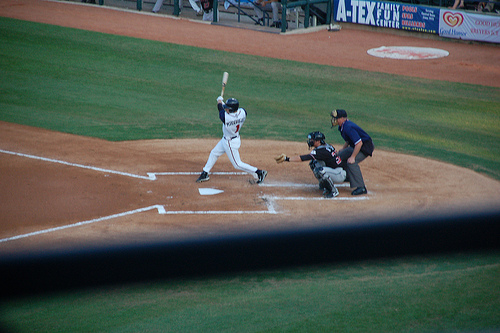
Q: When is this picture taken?
A: During game.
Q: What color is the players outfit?
A: White.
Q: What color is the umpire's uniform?
A: Blue and gray.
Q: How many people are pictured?
A: Three.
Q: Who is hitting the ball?
A: Baseball player.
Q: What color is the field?
A: Green.